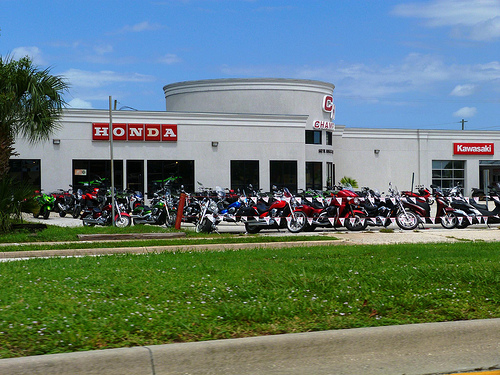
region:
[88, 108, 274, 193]
Red tiles on front of building.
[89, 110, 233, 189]
The word HONDA written on the red tiles.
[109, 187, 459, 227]
Many bikes lined up in front of the building.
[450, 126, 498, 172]
Kawasaki written on the building.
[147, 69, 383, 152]
Middle top section of building has a circular shape.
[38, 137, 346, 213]
Large windows in the front of the building.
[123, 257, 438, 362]
Green grass in front of building.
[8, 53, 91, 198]
Large tree near building.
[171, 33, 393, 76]
Blue sky in background.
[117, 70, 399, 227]
Building is light gray in color.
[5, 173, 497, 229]
motorcycles lined up for sale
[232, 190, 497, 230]
banner flags are in front of the motorcycles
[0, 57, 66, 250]
a palm tree at the side of the lot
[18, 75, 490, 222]
the building has a rotunda in the center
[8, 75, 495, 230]
the building is white with red signs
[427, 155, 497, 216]
garage doors on the front of the building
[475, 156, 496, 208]
an open garage door in front of the building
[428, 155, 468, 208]
a closed garage door in the front of the building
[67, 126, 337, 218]
the windows are dark in the building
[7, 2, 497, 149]
the sky is blue with white clouds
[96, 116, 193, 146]
a red and white sign on a business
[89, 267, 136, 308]
white flowers growing across the street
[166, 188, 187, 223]
a red pole marking the street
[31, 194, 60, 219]
a lime green motorcycle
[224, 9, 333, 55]
a clear blue sky overhead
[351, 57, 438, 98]
white wispsy clouds in the sky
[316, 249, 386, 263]
thick green grass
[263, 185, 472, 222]
motorcycles for sale at a dealership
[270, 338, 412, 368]
gray cement on the curb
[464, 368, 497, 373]
the edge of a yellow line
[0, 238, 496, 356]
A patch of green grass.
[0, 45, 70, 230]
A tall green palm tree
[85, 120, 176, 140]
A Honda sign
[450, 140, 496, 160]
A Kawasaki sign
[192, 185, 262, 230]
A blue motorcycle for sale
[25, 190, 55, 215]
A green motorcycle for sale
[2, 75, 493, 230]
A Honda motorcycle dealership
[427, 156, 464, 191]
A paneled window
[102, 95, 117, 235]
A metal pole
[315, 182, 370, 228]
a red motorcycle for sale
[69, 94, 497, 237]
rows of motorcycle at dealership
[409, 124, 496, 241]
Kawasaki sign with motorcyles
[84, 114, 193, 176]
Honda dealership sign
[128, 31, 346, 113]
rounded top of building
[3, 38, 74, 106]
palm tree against blue sky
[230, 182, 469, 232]
white pennant string in front of row of motorcycles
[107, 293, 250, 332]
green grass dotted with clover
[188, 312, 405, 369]
brown and green grass against curb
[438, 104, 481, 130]
telephone pole against blue sky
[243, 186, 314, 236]
red motorcycle with white pennant string